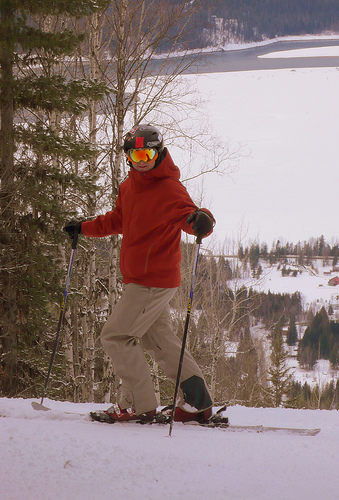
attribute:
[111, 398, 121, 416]
strap — silver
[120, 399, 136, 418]
strap — silver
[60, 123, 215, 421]
person — skiing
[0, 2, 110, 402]
evergreen tree — tall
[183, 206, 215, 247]
glove — black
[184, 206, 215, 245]
hand — person's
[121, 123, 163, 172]
helmet — black 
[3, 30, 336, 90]
river — open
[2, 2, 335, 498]
landscape — snow covered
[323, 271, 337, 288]
house — red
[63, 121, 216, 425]
skier — orange, stopped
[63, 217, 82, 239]
glove — black 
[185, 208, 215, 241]
glove — black 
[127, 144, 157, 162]
goggles — snow goggles, reflective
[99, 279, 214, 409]
pants — light brown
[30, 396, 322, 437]
skis — a pair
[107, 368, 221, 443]
boots — ski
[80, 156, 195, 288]
jacket — red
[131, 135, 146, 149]
sticker — red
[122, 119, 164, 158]
helmet — black 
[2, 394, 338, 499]
snow — covering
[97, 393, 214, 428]
ski boots — red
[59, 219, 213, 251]
handles — black 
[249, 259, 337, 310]
lodge — ski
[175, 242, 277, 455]
poles — ski poles